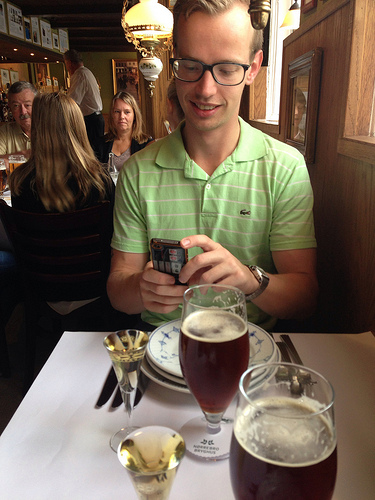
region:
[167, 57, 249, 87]
glasses with black frames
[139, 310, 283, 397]
circular plates behind the glass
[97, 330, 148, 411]
Three butter knives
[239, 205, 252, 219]
a logo on a striped shirt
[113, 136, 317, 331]
a shirt with a collar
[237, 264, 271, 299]
a watch on the man's left wrist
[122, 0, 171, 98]
a hanging light fixture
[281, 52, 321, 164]
a wooden frame on the wall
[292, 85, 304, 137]
a reflection on the picture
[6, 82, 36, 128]
the man has a gray mustache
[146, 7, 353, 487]
man sitting at table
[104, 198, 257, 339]
man holding cell phone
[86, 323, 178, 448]
small wine glass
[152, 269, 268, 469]
beer glass on table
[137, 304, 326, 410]
plates on table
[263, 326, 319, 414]
silver forks on table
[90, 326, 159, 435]
silver knifes on table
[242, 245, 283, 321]
man wearing silver watch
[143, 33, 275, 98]
man wearing black rimmed glasses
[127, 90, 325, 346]
man wearing green shirt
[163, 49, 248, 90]
the gut is wearing glasses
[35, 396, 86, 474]
the placemat is white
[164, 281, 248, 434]
the glass is full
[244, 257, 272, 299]
the guy is wearing a watch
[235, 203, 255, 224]
an alligator logo is on his shirt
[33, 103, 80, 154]
the womans hair is blonde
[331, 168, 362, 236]
the wall is brown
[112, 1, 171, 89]
the lamp is hanging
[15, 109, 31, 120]
the man has a mustache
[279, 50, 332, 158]
the picture is on the wall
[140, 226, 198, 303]
Hands holding a cell phone.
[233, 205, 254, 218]
Alligator on the shirt.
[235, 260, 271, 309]
Man wearing a watch.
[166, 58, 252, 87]
Smiling man wearing glasses.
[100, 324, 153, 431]
Gold cup beside the plate.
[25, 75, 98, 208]
Woman with long hair at the next table.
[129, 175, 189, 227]
Green shirt with white stripes.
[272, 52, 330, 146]
Mirror on the wall.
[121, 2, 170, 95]
Light hanging from the ceiling.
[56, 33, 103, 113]
Man at the bar ordering a drink.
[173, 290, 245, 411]
a glass of beer with a head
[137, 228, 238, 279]
a person holding a cellular phone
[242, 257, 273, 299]
a watch on a person's wrist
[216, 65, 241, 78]
the left eye of a person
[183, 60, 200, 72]
the right eye of a person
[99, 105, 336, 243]
a person wearing a green and white shirt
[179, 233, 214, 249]
the finger of a person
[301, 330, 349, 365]
a white table cloth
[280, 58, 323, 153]
a framed picture on the wall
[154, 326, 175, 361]
a white bowl with blue designs